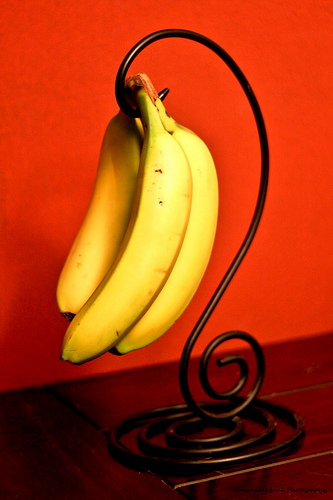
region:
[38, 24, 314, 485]
Bananas are on a hook.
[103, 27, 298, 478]
The hook is made of metal.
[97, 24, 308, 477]
The hook has many wires.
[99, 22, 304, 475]
The hook is very curvy.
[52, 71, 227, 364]
The bananas are yellow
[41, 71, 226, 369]
The bananas are bunched together.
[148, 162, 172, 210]
The banana has some brown spots on it.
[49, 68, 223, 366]
At least three bananas are on the hook.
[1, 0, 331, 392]
The wall in the background is red.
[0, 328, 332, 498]
The table is brown.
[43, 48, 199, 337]
small bunch of bananas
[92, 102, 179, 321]
three bananas in bunch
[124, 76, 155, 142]
yellow stems on bananas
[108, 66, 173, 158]
bananas on black hook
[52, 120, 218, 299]
yellow flesh on bananas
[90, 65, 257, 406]
black and metal hook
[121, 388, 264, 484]
black base on hook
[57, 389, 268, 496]
base on dark table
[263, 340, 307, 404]
table is dark brown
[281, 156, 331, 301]
red wall behind bananas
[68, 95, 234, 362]
three bananas in bunch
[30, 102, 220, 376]
three bananas are yellow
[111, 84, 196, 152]
yellow stem on bananas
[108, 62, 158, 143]
black and metal hook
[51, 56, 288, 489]
black hook on table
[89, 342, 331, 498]
table is dark brown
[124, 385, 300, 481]
hook has circular base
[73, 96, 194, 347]
yellow skin on bananas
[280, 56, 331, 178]
red wall behind bananas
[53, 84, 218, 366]
A bunch of ripe bananas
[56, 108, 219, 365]
Bunch of yellow colored bananas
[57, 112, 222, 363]
Bananas hanging on a hook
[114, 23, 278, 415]
A hook holding bananas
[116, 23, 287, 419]
A black colored metal hook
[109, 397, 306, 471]
A black metal coil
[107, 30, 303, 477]
Black hook on a coil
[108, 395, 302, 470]
Coil on wooden surface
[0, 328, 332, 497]
A red wooden surface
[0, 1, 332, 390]
An orange colored wall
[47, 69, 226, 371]
3 bananas 3 [unless theres a sneaky one behind]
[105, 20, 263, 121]
the curvy curled top of a banana hanger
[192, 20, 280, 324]
the s-curved middle of a banana hanger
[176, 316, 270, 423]
the curlicue bottom of a banana hanger that sits on its base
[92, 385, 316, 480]
the concentric spiral base of a banana hanger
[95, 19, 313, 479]
all banana hanger parts are made of twisted black metal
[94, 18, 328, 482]
entire banana hanger is made of two mazy parts: hanger+base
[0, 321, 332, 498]
a rosewood-stained counter or table [IRL or IRphotoshop];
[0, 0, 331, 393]
a lipstick firetruck orange red wall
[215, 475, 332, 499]
sig in right bottom corner so it's after licensing